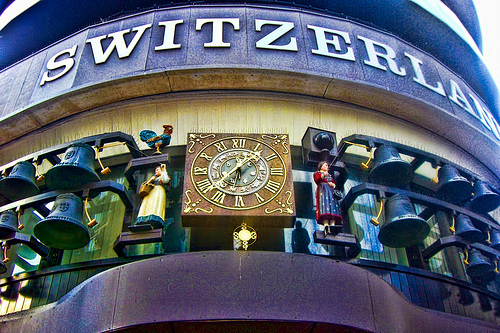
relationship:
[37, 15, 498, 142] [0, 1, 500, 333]
word on side of building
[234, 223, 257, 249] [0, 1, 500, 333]
light on front of building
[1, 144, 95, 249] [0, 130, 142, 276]
bells are in a group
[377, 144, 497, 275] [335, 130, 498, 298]
bells are in a group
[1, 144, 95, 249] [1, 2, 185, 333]
bells are on side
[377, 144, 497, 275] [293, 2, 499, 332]
bells are on side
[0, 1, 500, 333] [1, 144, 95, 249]
building has bells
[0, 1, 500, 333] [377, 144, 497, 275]
building has bells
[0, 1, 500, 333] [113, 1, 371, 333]
building has face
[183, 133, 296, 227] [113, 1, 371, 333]
clock on face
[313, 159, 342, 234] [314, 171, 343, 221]
figure in dress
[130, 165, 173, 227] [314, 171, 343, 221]
figure in dress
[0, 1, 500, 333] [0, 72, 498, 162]
building has underside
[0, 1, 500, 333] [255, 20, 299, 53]
building has a letter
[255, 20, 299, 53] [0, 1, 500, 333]
letter on building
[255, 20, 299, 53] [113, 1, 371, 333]
letter on front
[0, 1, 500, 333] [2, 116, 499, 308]
building has facade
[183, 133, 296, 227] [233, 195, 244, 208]
clock has roman numeral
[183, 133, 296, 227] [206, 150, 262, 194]
clock has hands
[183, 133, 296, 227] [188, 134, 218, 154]
clock has corner corner design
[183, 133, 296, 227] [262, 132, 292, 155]
clock has corner design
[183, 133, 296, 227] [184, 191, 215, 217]
clock has corner design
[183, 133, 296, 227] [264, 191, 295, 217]
clock has corner design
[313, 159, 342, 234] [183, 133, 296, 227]
figure stands on side of clock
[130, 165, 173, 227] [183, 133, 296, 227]
figure stands on side of clock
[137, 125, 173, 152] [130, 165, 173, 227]
rooster stands above figure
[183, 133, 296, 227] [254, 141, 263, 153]
clock has roman numeral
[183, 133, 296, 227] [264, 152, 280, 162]
clock has roman numeral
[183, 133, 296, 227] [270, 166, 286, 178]
clock has roman numeral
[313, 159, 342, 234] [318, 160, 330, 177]
figure on dplay female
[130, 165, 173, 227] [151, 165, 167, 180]
figure on dplay female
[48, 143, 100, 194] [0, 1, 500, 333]
bell hanging on building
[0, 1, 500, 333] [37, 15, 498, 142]
building has white text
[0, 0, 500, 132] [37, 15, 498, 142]
background has letters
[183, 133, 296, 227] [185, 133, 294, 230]
clock has background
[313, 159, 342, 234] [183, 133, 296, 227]
statue next to clock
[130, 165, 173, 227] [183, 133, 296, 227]
statue next to clock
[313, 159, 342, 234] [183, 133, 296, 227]
statue near clock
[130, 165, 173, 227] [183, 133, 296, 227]
statue near clock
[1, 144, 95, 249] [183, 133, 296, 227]
bells next to clock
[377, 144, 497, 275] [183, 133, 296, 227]
bells next to clock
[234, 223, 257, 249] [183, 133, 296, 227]
pendulum under clock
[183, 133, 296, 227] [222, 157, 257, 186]
clock has center